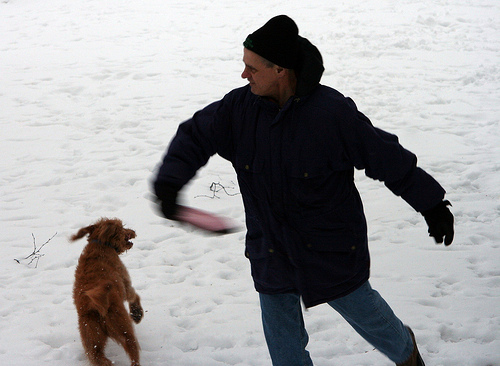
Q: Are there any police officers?
A: No, there are no police officers.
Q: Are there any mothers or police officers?
A: No, there are no police officers or mothers.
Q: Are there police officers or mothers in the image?
A: No, there are no police officers or mothers.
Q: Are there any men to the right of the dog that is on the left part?
A: Yes, there is a man to the right of the dog.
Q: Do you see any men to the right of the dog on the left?
A: Yes, there is a man to the right of the dog.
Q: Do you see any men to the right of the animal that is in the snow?
A: Yes, there is a man to the right of the dog.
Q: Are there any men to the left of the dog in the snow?
A: No, the man is to the right of the dog.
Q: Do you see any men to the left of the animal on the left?
A: No, the man is to the right of the dog.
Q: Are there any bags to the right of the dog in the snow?
A: No, there is a man to the right of the dog.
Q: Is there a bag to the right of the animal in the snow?
A: No, there is a man to the right of the dog.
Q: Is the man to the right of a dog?
A: Yes, the man is to the right of a dog.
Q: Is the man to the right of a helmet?
A: No, the man is to the right of a dog.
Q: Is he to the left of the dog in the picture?
A: No, the man is to the right of the dog.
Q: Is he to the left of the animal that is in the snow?
A: No, the man is to the right of the dog.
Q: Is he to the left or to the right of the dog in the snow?
A: The man is to the right of the dog.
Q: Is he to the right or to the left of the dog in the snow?
A: The man is to the right of the dog.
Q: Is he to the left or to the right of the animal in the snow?
A: The man is to the right of the dog.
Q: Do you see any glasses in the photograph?
A: No, there are no glasses.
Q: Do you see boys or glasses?
A: No, there are no glasses or boys.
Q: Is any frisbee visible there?
A: Yes, there is a frisbee.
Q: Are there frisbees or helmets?
A: Yes, there is a frisbee.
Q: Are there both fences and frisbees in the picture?
A: No, there is a frisbee but no fences.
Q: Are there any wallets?
A: No, there are no wallets.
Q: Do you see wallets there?
A: No, there are no wallets.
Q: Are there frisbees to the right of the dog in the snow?
A: Yes, there is a frisbee to the right of the dog.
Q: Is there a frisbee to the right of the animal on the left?
A: Yes, there is a frisbee to the right of the dog.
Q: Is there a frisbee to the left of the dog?
A: No, the frisbee is to the right of the dog.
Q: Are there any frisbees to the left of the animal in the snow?
A: No, the frisbee is to the right of the dog.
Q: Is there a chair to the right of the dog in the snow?
A: No, there is a frisbee to the right of the dog.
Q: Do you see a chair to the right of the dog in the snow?
A: No, there is a frisbee to the right of the dog.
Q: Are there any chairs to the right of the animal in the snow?
A: No, there is a frisbee to the right of the dog.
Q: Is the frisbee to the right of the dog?
A: Yes, the frisbee is to the right of the dog.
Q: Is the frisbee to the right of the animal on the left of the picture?
A: Yes, the frisbee is to the right of the dog.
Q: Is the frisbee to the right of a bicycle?
A: No, the frisbee is to the right of the dog.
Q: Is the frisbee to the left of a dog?
A: No, the frisbee is to the right of a dog.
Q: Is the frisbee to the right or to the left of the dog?
A: The frisbee is to the right of the dog.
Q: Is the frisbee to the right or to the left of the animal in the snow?
A: The frisbee is to the right of the dog.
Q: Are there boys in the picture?
A: No, there are no boys.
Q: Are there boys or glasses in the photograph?
A: No, there are no boys or glasses.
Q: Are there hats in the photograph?
A: Yes, there is a hat.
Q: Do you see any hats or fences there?
A: Yes, there is a hat.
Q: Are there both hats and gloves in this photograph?
A: Yes, there are both a hat and gloves.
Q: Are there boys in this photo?
A: No, there are no boys.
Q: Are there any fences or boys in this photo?
A: No, there are no boys or fences.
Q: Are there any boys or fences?
A: No, there are no boys or fences.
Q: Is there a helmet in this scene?
A: No, there are no helmets.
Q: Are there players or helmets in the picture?
A: No, there are no helmets or players.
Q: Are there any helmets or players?
A: No, there are no helmets or players.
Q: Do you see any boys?
A: No, there are no boys.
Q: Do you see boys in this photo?
A: No, there are no boys.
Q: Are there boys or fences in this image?
A: No, there are no boys or fences.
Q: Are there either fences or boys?
A: No, there are no boys or fences.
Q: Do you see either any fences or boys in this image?
A: No, there are no boys or fences.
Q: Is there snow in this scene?
A: Yes, there is snow.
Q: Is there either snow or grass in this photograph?
A: Yes, there is snow.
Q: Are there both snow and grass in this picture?
A: No, there is snow but no grass.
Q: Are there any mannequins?
A: No, there are no mannequins.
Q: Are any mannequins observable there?
A: No, there are no mannequins.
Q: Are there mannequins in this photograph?
A: No, there are no mannequins.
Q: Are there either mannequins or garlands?
A: No, there are no mannequins or garlands.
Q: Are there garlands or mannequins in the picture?
A: No, there are no mannequins or garlands.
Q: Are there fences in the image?
A: No, there are no fences.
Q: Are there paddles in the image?
A: No, there are no paddles.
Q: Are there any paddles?
A: No, there are no paddles.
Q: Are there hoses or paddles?
A: No, there are no paddles or hoses.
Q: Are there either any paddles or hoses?
A: No, there are no paddles or hoses.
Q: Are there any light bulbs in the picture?
A: No, there are no light bulbs.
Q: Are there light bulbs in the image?
A: No, there are no light bulbs.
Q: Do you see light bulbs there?
A: No, there are no light bulbs.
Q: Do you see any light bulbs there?
A: No, there are no light bulbs.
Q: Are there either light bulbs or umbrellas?
A: No, there are no light bulbs or umbrellas.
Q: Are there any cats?
A: No, there are no cats.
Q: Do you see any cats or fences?
A: No, there are no cats or fences.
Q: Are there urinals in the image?
A: No, there are no urinals.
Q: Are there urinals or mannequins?
A: No, there are no urinals or mannequins.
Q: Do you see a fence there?
A: No, there are no fences.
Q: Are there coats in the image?
A: Yes, there is a coat.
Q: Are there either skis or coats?
A: Yes, there is a coat.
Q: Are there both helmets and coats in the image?
A: No, there is a coat but no helmets.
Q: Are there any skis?
A: No, there are no skis.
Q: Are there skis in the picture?
A: No, there are no skis.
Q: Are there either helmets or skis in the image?
A: No, there are no skis or helmets.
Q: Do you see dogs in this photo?
A: Yes, there is a dog.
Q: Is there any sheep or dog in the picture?
A: Yes, there is a dog.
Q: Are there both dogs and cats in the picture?
A: No, there is a dog but no cats.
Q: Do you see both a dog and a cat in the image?
A: No, there is a dog but no cats.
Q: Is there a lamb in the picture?
A: No, there are no lambs.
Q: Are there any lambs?
A: No, there are no lambs.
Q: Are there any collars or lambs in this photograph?
A: No, there are no lambs or collars.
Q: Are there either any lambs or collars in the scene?
A: No, there are no lambs or collars.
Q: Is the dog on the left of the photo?
A: Yes, the dog is on the left of the image.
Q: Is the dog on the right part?
A: No, the dog is on the left of the image.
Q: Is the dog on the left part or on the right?
A: The dog is on the left of the image.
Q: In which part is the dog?
A: The dog is on the left of the image.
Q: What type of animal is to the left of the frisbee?
A: The animal is a dog.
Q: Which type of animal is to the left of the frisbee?
A: The animal is a dog.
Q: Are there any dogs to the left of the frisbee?
A: Yes, there is a dog to the left of the frisbee.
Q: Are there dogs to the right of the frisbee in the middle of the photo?
A: No, the dog is to the left of the frisbee.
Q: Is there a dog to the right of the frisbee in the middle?
A: No, the dog is to the left of the frisbee.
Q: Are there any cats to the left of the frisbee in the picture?
A: No, there is a dog to the left of the frisbee.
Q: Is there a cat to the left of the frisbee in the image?
A: No, there is a dog to the left of the frisbee.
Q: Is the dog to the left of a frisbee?
A: Yes, the dog is to the left of a frisbee.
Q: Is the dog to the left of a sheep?
A: No, the dog is to the left of a frisbee.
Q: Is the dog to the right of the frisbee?
A: No, the dog is to the left of the frisbee.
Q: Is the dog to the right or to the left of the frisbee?
A: The dog is to the left of the frisbee.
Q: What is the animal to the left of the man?
A: The animal is a dog.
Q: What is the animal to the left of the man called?
A: The animal is a dog.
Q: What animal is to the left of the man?
A: The animal is a dog.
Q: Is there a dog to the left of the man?
A: Yes, there is a dog to the left of the man.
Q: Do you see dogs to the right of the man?
A: No, the dog is to the left of the man.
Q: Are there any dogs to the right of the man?
A: No, the dog is to the left of the man.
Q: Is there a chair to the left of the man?
A: No, there is a dog to the left of the man.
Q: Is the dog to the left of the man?
A: Yes, the dog is to the left of the man.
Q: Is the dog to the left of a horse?
A: No, the dog is to the left of the man.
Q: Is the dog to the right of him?
A: No, the dog is to the left of the man.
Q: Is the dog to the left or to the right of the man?
A: The dog is to the left of the man.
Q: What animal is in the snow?
A: The animal is a dog.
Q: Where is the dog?
A: The dog is in the snow.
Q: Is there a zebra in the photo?
A: No, there are no zebras.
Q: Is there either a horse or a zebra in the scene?
A: No, there are no zebras or horses.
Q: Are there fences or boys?
A: No, there are no boys or fences.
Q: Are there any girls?
A: No, there are no girls.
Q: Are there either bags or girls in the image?
A: No, there are no girls or bags.